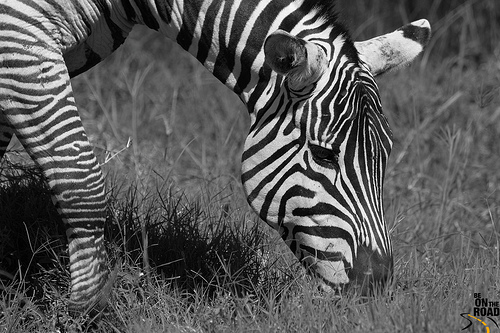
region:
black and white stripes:
[215, 40, 422, 315]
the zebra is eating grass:
[213, 115, 400, 327]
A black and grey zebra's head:
[263, 89, 405, 291]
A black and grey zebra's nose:
[374, 262, 391, 284]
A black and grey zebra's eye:
[303, 137, 333, 172]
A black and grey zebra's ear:
[268, 31, 318, 87]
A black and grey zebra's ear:
[355, 15, 428, 73]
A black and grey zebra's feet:
[56, 180, 124, 325]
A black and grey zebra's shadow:
[114, 209, 261, 284]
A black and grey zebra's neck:
[122, 4, 249, 96]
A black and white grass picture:
[405, 171, 461, 327]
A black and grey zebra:
[0, 4, 394, 314]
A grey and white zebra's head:
[234, 105, 389, 280]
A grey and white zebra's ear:
[271, 21, 327, 111]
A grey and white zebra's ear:
[357, 31, 432, 77]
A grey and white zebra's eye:
[302, 129, 344, 171]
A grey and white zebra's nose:
[348, 269, 397, 284]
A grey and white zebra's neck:
[110, 4, 262, 112]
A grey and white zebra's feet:
[50, 168, 116, 302]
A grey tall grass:
[163, 196, 259, 311]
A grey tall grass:
[422, 96, 475, 282]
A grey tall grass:
[125, 80, 201, 277]